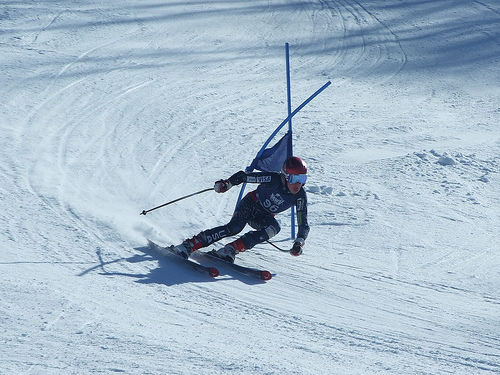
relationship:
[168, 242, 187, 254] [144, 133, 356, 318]
foot of skier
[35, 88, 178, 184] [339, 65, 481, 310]
tracks in snow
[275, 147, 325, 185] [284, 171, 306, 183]
helmet with goggles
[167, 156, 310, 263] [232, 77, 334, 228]
racer has just hit banner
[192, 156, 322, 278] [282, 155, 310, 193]
person wearing a helmet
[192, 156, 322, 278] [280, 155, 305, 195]
person has head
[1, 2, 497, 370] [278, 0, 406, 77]
snow has tracks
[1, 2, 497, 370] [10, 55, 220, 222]
snow has tracks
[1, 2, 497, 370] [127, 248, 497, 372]
snow has tracks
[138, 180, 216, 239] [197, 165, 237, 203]
ski pole on hand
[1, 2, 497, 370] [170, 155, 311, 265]
snow behind skier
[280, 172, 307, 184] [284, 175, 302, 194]
goggles on face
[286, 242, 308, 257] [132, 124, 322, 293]
hand on skier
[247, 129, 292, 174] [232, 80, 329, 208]
flag on pole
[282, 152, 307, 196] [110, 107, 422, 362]
head of person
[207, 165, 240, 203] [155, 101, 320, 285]
hand of skier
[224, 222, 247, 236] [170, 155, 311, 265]
knee of skier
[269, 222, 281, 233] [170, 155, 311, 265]
knee of skier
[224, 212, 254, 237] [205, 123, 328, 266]
knee of skier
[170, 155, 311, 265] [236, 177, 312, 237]
skier has chest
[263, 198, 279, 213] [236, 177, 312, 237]
number 36 on chest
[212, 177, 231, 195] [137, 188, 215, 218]
right hand holds ski pole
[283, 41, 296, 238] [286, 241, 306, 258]
pole bent in left hand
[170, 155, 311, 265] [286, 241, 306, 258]
skier has left hand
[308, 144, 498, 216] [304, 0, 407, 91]
snow`s clumps off track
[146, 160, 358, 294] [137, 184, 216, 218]
person holding ski pole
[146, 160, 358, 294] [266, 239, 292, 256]
person holding ski pole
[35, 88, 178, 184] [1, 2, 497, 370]
tracks in snow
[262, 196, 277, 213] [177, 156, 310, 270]
96 on racer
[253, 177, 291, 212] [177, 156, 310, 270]
torso of racer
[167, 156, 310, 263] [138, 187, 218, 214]
racer holding pole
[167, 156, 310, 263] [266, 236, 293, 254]
racer holding pole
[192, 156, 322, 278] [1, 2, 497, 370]
person on snow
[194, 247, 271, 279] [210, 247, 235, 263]
ski on foot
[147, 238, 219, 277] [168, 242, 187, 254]
ski on foot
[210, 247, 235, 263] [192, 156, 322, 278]
foot of person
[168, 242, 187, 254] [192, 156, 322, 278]
foot of person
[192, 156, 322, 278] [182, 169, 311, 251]
person wearing outfit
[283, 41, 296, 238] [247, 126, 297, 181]
pole holding flag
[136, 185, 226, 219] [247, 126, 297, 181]
pole holding flag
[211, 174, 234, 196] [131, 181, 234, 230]
hand holding ski pole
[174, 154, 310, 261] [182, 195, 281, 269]
man wearing ski pants